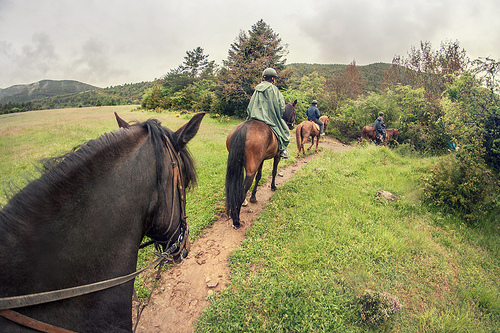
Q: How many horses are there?
A: 4.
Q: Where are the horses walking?
A: On the path.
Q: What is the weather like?
A: Overcast.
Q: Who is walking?
A: The horses.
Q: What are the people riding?
A: Horses.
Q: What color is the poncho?
A: Green.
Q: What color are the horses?
A: Brown.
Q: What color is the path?
A: Brown.